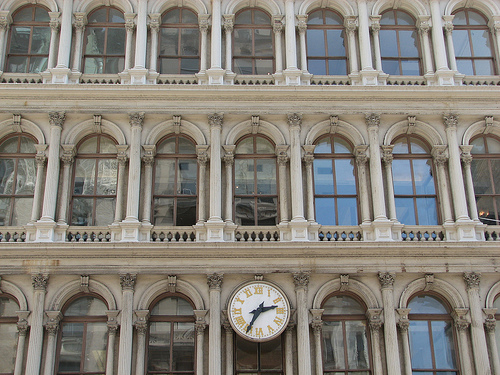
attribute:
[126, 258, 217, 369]
frames — window, brown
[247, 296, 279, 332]
hands — black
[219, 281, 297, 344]
clock — one 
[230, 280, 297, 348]
clock — one 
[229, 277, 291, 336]
numerals — Roman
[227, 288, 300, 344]
numerals — Roman, gold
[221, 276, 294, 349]
clock — one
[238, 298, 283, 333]
hands — clock, black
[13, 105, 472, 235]
windows — arched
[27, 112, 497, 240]
windows — framed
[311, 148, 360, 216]
sky — blue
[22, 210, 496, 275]
balconies — tan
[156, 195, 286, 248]
railings — decorative